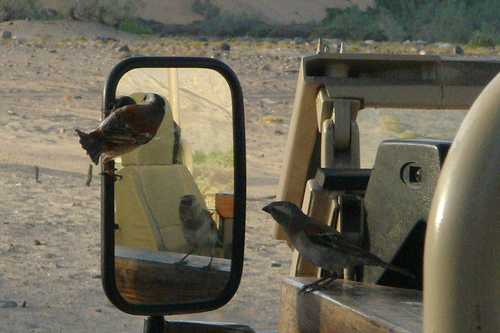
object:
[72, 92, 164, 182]
bird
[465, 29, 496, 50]
plants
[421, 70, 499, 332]
surface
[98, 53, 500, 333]
vehicle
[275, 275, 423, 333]
box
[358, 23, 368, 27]
leaves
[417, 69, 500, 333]
rail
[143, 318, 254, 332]
arm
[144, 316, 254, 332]
stand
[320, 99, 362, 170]
hinge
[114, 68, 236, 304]
mirror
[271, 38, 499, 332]
car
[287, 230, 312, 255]
chest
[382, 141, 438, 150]
reflection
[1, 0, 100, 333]
white sand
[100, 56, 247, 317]
frame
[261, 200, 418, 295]
bird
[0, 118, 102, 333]
dirt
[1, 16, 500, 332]
ground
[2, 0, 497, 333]
sand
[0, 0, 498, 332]
dirt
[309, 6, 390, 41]
tree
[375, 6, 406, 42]
tree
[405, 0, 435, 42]
tree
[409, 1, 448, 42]
tree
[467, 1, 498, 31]
tree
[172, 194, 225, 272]
bird